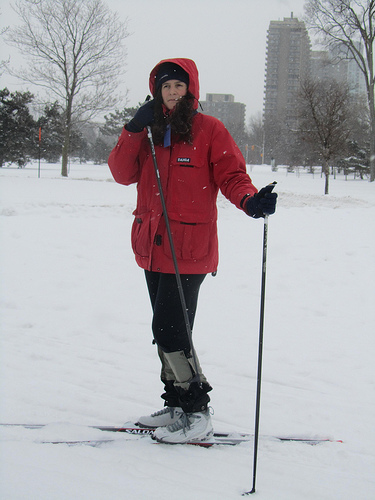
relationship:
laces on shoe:
[166, 414, 192, 430] [154, 412, 221, 434]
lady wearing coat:
[107, 56, 280, 446] [108, 55, 256, 276]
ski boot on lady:
[147, 415, 220, 449] [132, 50, 210, 134]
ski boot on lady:
[132, 407, 177, 427] [132, 50, 210, 134]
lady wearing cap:
[104, 52, 271, 445] [151, 63, 189, 90]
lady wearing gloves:
[107, 56, 280, 446] [125, 97, 156, 132]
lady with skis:
[107, 56, 280, 446] [89, 427, 313, 446]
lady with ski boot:
[107, 56, 280, 446] [151, 410, 221, 448]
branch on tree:
[0, 58, 62, 103] [3, 2, 130, 176]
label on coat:
[175, 156, 189, 162] [83, 51, 282, 277]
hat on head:
[155, 62, 190, 89] [161, 78, 187, 111]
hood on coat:
[145, 57, 201, 118] [61, 50, 309, 270]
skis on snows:
[3, 425, 348, 451] [1, 157, 371, 497]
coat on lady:
[108, 55, 256, 276] [107, 56, 280, 446]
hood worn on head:
[145, 53, 199, 118] [157, 72, 189, 111]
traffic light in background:
[248, 131, 267, 166] [1, 0, 371, 174]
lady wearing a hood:
[104, 52, 271, 445] [145, 57, 201, 118]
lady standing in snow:
[107, 56, 280, 446] [1, 158, 374, 498]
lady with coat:
[107, 56, 280, 446] [112, 50, 253, 295]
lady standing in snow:
[107, 56, 280, 446] [63, 435, 241, 499]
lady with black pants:
[107, 56, 280, 446] [139, 264, 218, 409]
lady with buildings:
[107, 56, 280, 446] [245, 10, 322, 164]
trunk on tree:
[59, 103, 74, 171] [21, 6, 110, 194]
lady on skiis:
[107, 56, 280, 446] [20, 410, 345, 471]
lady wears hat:
[107, 56, 280, 446] [155, 62, 190, 89]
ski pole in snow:
[248, 200, 271, 491] [1, 158, 374, 498]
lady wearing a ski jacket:
[104, 52, 271, 445] [108, 54, 254, 274]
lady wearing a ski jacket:
[104, 52, 271, 445] [108, 50, 259, 272]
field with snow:
[5, 170, 353, 495] [1, 158, 374, 498]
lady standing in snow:
[107, 56, 280, 446] [11, 193, 115, 362]